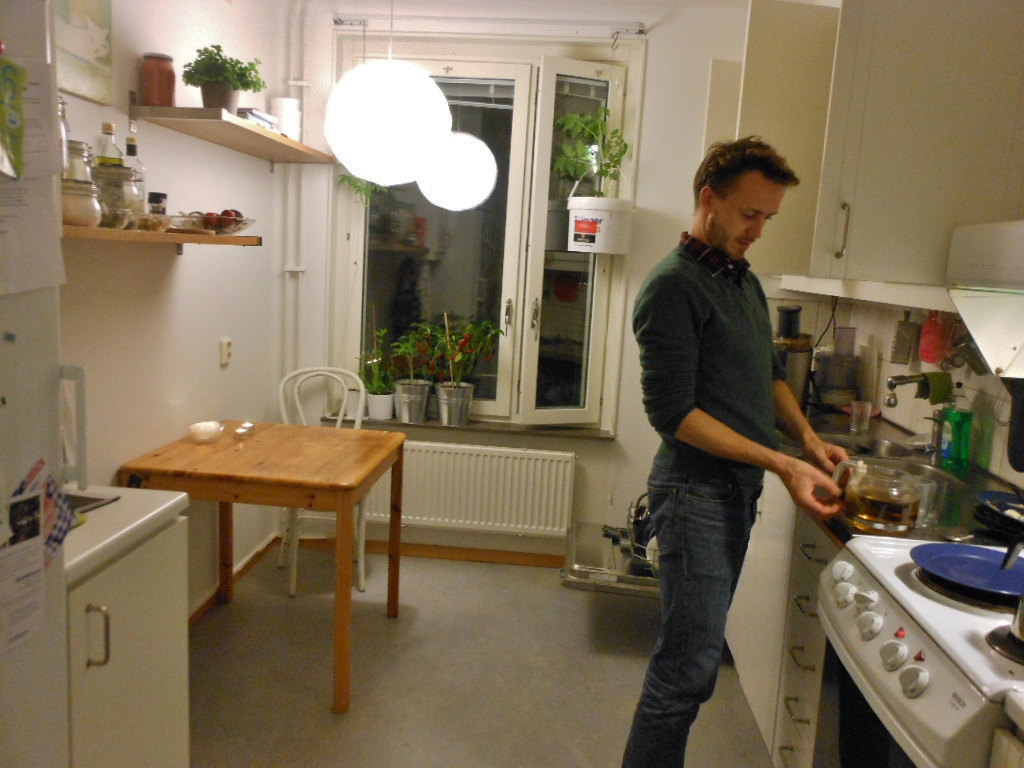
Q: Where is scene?
A: In a kitchen.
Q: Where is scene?
A: The kitchen.